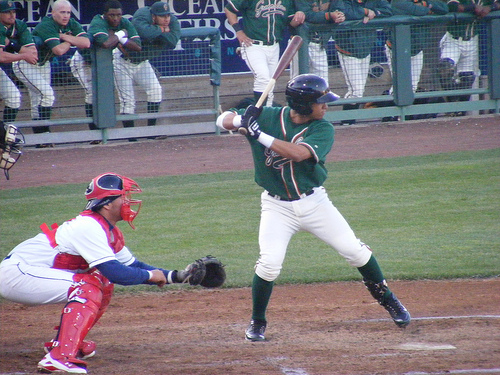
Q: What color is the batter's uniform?
A: Green.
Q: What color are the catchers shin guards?
A: Red.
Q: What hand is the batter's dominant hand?
A: Right.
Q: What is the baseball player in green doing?
A: Swinging a bat.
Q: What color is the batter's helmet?
A: Black.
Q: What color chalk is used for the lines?
A: White.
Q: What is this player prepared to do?
A: Hit the ball.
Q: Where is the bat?
A: Over the player's left shoulder.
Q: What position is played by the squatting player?
A: Catcher.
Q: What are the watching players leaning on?
A: A grilled fence.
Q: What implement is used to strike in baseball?
A: A bat.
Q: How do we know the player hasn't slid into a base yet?
A: His pants are white and clean.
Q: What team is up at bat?
A: The green team.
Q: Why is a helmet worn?
A: To protect the players head.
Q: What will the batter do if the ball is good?
A: Run to first base.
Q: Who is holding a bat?
A: The batter.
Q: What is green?
A: Grass.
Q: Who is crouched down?
A: The catcher.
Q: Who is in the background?
A: Players.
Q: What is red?
A: Leg protection on catcher.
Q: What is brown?
A: Dirt.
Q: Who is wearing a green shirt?
A: The batter.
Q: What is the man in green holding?
A: A bat.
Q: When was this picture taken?
A: Daytime.